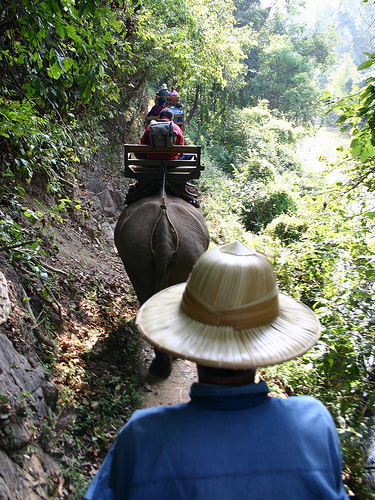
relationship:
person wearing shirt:
[79, 238, 351, 496] [78, 377, 350, 498]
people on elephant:
[147, 87, 175, 138] [105, 195, 214, 295]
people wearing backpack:
[140, 107, 185, 160] [149, 128, 178, 140]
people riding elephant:
[140, 107, 185, 160] [103, 90, 236, 381]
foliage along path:
[6, 0, 252, 174] [31, 127, 137, 476]